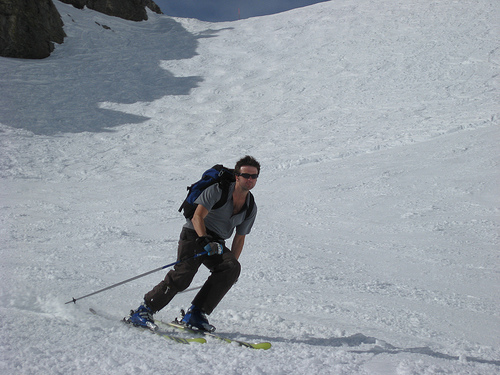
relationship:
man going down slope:
[124, 153, 263, 336] [0, 1, 489, 373]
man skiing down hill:
[124, 153, 263, 336] [58, 6, 328, 373]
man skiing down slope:
[124, 153, 263, 336] [0, 1, 489, 373]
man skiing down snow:
[124, 153, 263, 336] [310, 95, 475, 217]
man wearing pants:
[124, 153, 263, 336] [143, 226, 242, 312]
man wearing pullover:
[124, 153, 263, 336] [183, 179, 258, 242]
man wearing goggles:
[124, 153, 263, 336] [237, 172, 259, 179]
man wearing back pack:
[124, 153, 263, 336] [176, 164, 234, 220]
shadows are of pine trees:
[7, 30, 239, 140] [0, 3, 163, 66]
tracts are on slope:
[4, 10, 493, 373] [0, 1, 489, 373]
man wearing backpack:
[124, 153, 263, 336] [182, 161, 233, 231]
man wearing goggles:
[124, 153, 263, 336] [233, 168, 258, 178]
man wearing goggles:
[124, 153, 263, 336] [237, 168, 262, 180]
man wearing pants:
[122, 154, 293, 324] [135, 250, 282, 340]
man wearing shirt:
[124, 153, 263, 336] [180, 158, 268, 264]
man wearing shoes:
[124, 153, 263, 336] [130, 295, 212, 336]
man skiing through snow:
[124, 153, 263, 336] [391, 70, 473, 88]